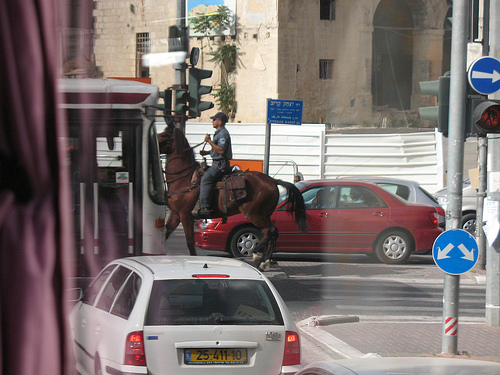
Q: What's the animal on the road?
A: Horse.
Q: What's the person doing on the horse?
A: Riding it.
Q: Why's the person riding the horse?
A: For transportation.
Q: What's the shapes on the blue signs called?
A: Arrow.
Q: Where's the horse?
A: Middle of the road.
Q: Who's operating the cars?
A: The people.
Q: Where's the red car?
A: Next to the horse.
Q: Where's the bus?
A: Next to horse.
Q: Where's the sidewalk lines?
A: On the road.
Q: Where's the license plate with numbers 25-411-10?
A: Back of white car.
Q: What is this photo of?
A: Traffic.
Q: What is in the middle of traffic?
A: A horse.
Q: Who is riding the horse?
A: A man.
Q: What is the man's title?
A: An officer.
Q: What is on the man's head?
A: A hat.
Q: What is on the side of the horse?
A: A car.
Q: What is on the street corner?
A: A pole.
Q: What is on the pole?
A: A sign.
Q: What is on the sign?
A: Arrows.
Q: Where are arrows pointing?
A: Left and right.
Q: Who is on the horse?
A: Police man.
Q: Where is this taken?
A: In a city.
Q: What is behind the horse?
A: Red car.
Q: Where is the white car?
A: In front of the horse.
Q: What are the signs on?
A: Poles.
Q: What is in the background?
A: Buildings.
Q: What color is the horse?
A: Brown.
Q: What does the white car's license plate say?
A: 25-411-10.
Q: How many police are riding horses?
A: 1.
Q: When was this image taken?
A: Daytime.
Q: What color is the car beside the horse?
A: Red.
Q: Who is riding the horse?
A: The policeman.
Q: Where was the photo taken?
A: At a street.